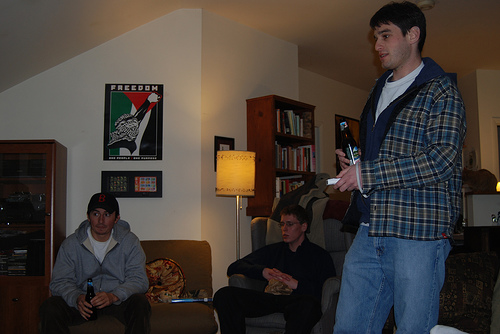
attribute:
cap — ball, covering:
[77, 193, 128, 223]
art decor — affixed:
[106, 82, 162, 159]